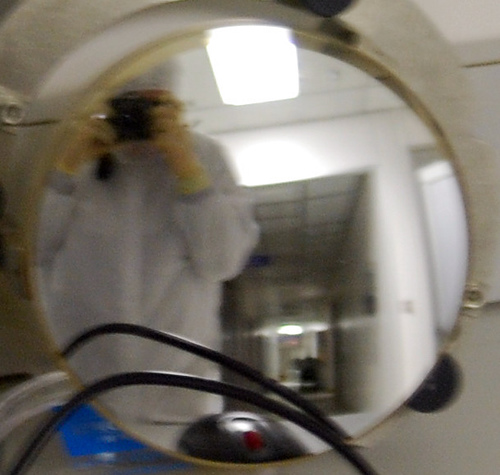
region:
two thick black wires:
[10, 315, 375, 473]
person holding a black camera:
[48, 80, 273, 421]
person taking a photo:
[47, 65, 328, 450]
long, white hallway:
[227, 235, 379, 427]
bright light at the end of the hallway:
[276, 320, 313, 336]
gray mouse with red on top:
[159, 392, 317, 468]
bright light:
[204, 27, 319, 114]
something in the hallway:
[286, 348, 333, 398]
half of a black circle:
[412, 358, 461, 415]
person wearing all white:
[29, 56, 281, 453]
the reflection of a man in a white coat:
[48, 56, 250, 416]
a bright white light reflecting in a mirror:
[194, 47, 306, 107]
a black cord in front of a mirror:
[72, 366, 289, 421]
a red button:
[234, 423, 268, 457]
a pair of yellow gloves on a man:
[75, 112, 199, 181]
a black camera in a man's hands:
[100, 88, 163, 154]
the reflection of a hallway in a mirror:
[193, 170, 399, 432]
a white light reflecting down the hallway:
[270, 316, 310, 351]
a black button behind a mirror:
[392, 353, 472, 415]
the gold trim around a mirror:
[450, 176, 477, 206]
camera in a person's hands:
[99, 88, 159, 146]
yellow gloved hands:
[51, 105, 213, 198]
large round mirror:
[16, 19, 482, 474]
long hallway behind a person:
[208, 265, 349, 412]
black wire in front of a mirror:
[5, 363, 405, 473]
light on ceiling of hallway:
[269, 317, 304, 337]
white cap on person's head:
[106, 50, 198, 105]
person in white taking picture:
[32, 44, 248, 450]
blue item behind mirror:
[46, 394, 189, 468]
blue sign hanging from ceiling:
[236, 245, 278, 275]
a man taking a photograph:
[53, 78, 203, 181]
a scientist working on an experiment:
[21, 50, 302, 443]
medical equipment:
[0, 303, 368, 468]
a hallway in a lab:
[201, 220, 361, 420]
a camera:
[98, 91, 171, 154]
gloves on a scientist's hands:
[40, 82, 255, 216]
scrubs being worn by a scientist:
[35, 124, 277, 432]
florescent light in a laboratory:
[197, 13, 314, 115]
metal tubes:
[51, 312, 288, 469]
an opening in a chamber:
[14, 16, 493, 464]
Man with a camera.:
[79, 71, 234, 171]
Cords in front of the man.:
[91, 289, 408, 456]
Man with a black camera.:
[55, 88, 225, 179]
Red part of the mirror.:
[148, 357, 368, 472]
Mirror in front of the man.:
[24, 131, 486, 427]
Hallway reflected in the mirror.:
[251, 270, 396, 410]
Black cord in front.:
[10, 300, 318, 421]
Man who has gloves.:
[31, 54, 243, 226]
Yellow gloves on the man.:
[63, 77, 388, 293]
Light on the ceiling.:
[191, 24, 372, 159]